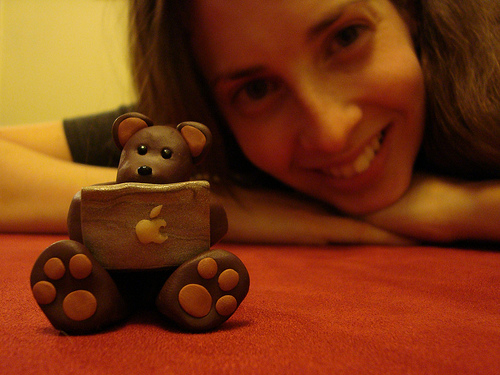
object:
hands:
[179, 167, 417, 248]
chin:
[322, 180, 407, 217]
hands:
[242, 159, 480, 242]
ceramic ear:
[176, 121, 211, 166]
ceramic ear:
[111, 112, 154, 152]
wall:
[0, 4, 124, 111]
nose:
[274, 60, 366, 156]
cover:
[60, 185, 227, 274]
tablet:
[78, 176, 213, 268]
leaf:
[149, 205, 164, 219]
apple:
[135, 204, 168, 244]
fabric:
[1, 230, 497, 373]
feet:
[160, 248, 251, 328]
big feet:
[29, 239, 114, 334]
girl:
[0, 0, 500, 242]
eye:
[228, 70, 286, 115]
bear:
[28, 112, 251, 334]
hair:
[399, 0, 497, 183]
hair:
[126, 0, 280, 203]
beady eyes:
[136, 144, 148, 156]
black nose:
[137, 165, 153, 177]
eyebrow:
[206, 60, 266, 95]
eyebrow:
[306, 0, 380, 43]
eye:
[320, 20, 377, 60]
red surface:
[2, 232, 499, 369]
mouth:
[295, 121, 402, 195]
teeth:
[304, 127, 389, 178]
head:
[107, 105, 217, 187]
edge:
[80, 181, 212, 203]